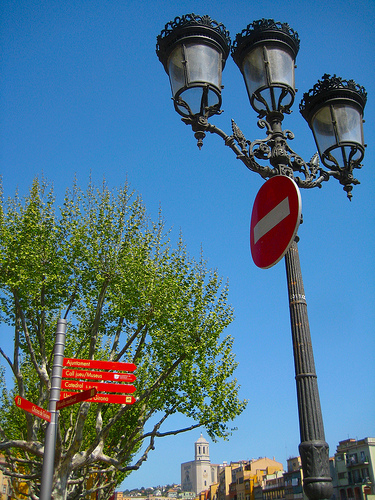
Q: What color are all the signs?
A: Red.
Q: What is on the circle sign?
A: A minus.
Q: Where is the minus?
A: On a sign.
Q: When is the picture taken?
A: Daytime.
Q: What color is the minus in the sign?
A: White.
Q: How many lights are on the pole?
A: 3.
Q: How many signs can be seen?
A: 7.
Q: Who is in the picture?
A: No one.